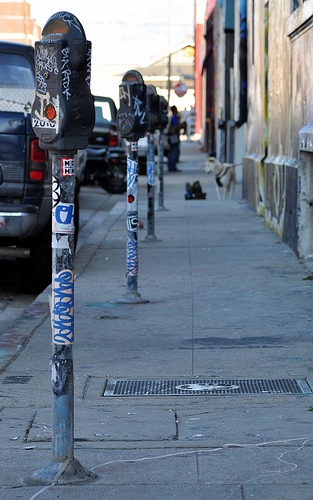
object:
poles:
[22, 153, 97, 486]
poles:
[111, 142, 150, 303]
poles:
[140, 132, 162, 241]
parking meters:
[114, 68, 149, 143]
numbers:
[33, 119, 55, 127]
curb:
[0, 191, 122, 378]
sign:
[173, 79, 186, 98]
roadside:
[0, 168, 126, 377]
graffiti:
[61, 45, 73, 101]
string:
[28, 435, 313, 500]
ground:
[0, 137, 313, 499]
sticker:
[52, 202, 76, 234]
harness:
[215, 162, 243, 180]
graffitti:
[265, 51, 281, 141]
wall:
[232, 0, 313, 264]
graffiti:
[0, 324, 28, 359]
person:
[167, 105, 180, 171]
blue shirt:
[171, 116, 177, 126]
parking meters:
[30, 10, 95, 153]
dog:
[205, 157, 237, 200]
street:
[1, 112, 312, 497]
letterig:
[61, 158, 74, 178]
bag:
[89, 162, 126, 193]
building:
[193, 0, 313, 259]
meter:
[30, 11, 96, 486]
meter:
[115, 69, 149, 303]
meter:
[141, 84, 163, 242]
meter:
[154, 95, 169, 211]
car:
[85, 95, 127, 184]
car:
[0, 38, 88, 290]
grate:
[104, 377, 311, 396]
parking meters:
[146, 83, 160, 131]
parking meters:
[157, 94, 168, 130]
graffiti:
[119, 84, 147, 124]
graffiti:
[146, 159, 155, 185]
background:
[62, 158, 65, 175]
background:
[55, 116, 60, 135]